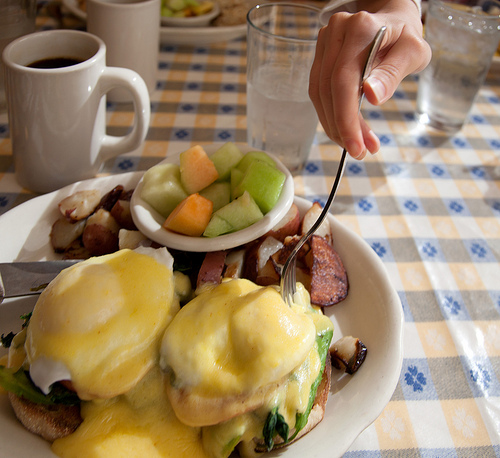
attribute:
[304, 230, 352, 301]
sausage — sliced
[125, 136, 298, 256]
bowl — small, fruit, white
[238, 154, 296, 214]
honeydew — small, chunk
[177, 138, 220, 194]
cantaloupe — chunk, small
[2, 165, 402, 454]
plate — round, white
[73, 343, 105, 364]
sauce — hollandaise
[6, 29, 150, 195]
cup — small, coffee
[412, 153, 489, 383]
tablecloth — pattern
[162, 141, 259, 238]
fruit — salad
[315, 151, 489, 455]
tablecloth — blue, yellow, checked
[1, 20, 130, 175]
mug — white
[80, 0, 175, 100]
mug — white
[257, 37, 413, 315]
fork — metal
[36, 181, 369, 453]
plate — large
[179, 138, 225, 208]
melon — orange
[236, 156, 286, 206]
melon — green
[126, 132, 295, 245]
melon — green, orange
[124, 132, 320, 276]
bowl — white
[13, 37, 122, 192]
mug — white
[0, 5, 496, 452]
tablecloth — yellow, blue, white, designed 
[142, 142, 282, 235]
fruit — cut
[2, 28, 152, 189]
coffee mug — white 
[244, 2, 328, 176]
cup — clear, tall, glass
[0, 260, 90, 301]
knife — silver